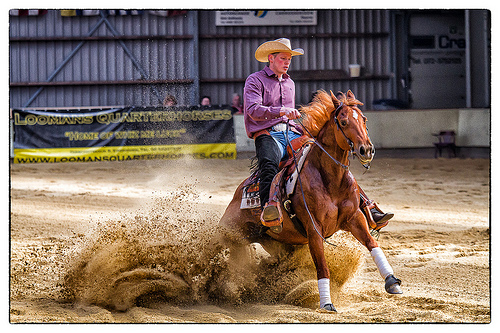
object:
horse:
[213, 89, 404, 311]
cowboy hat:
[254, 38, 305, 62]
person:
[243, 38, 394, 233]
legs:
[305, 213, 342, 314]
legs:
[256, 129, 289, 234]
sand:
[10, 152, 491, 322]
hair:
[297, 88, 343, 138]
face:
[275, 51, 292, 72]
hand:
[280, 106, 302, 121]